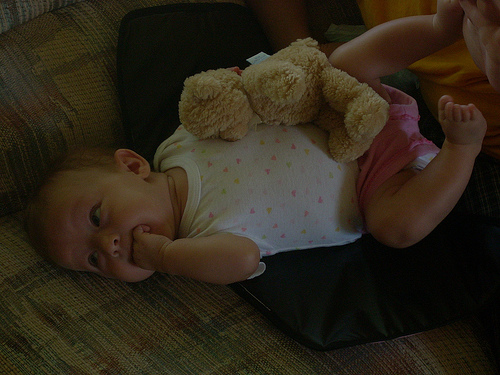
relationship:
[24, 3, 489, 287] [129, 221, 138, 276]
baby has mouth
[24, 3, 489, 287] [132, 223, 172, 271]
baby has hand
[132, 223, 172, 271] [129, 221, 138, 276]
hand inside mouth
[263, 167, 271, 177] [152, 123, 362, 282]
heart on onesie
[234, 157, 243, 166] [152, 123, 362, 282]
heart on onesie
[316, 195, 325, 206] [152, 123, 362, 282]
heart on onesie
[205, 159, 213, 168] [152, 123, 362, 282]
heart on onesie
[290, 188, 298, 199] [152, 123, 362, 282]
heart on onesie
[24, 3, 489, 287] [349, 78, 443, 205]
baby wearing shorts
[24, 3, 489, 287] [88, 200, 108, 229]
baby has eye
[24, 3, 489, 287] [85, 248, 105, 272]
baby has eye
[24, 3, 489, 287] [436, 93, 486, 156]
baby has foot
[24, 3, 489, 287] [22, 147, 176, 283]
baby has head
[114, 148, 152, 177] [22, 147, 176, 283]
ear part of head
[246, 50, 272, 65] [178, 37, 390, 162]
tag on top of teddy bear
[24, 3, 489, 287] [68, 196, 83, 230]
baby has eyebrow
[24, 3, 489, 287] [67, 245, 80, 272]
baby has eyebrow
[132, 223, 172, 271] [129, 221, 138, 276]
hand inside of mouth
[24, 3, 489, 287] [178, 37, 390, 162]
baby has teddy bear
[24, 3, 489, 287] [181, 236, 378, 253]
baby lying on back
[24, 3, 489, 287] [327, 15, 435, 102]
baby has leg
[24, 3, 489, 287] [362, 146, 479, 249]
baby has leg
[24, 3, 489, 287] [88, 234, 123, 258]
baby has nose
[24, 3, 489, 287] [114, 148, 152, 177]
baby has ear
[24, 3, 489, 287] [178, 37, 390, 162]
baby holding teddy bear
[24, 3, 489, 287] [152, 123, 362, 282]
baby wearing onesie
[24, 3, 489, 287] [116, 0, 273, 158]
baby lying on object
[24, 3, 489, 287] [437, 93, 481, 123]
baby has toes